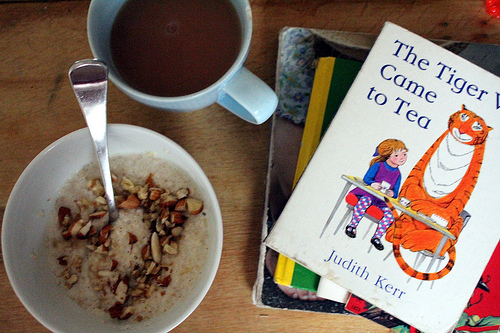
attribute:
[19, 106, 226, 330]
bowl — white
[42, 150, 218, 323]
food — breakfast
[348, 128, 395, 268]
girl — little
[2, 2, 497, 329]
table — wooden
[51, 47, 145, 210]
spoon — silver, shinny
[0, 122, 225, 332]
bowl — small, white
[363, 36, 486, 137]
writing — blue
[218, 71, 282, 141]
handle — blue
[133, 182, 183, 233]
nuts — chopped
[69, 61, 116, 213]
spoon — silver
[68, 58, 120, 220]
spoon handle — silver, metal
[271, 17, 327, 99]
book corner — worn out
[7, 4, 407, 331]
table — wood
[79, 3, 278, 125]
cup — blue